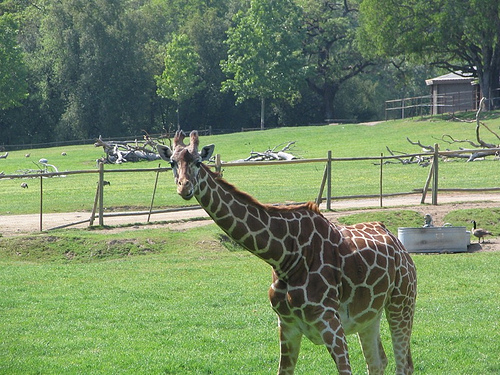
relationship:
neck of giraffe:
[159, 133, 313, 258] [159, 130, 419, 371]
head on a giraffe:
[165, 126, 225, 202] [145, 112, 444, 357]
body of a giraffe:
[289, 197, 429, 351] [145, 112, 444, 357]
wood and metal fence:
[91, 152, 117, 233] [7, 147, 493, 235]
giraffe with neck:
[148, 101, 428, 370] [209, 163, 296, 263]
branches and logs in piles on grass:
[88, 125, 169, 164] [139, 260, 188, 316]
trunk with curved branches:
[393, 92, 498, 160] [390, 129, 450, 167]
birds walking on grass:
[18, 131, 77, 190] [75, 284, 161, 337]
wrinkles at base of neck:
[265, 237, 310, 277] [205, 159, 321, 291]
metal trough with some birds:
[399, 220, 478, 250] [417, 208, 441, 224]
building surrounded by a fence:
[415, 66, 493, 119] [376, 84, 491, 111]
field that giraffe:
[11, 232, 484, 364] [145, 112, 444, 357]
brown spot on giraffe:
[273, 223, 283, 234] [145, 112, 444, 357]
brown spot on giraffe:
[305, 249, 318, 261] [145, 112, 444, 357]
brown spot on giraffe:
[272, 213, 288, 243] [164, 117, 438, 357]